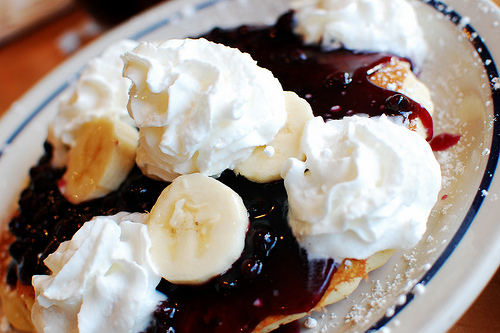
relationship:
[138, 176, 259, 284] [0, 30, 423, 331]
banana on pancake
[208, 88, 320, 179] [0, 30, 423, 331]
banana on pancake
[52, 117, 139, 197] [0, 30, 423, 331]
banana on pancake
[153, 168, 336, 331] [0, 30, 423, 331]
jelly on pancake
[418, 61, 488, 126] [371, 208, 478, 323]
sugar on plate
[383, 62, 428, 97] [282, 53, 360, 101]
pancake with syrup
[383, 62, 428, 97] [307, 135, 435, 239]
pancake with whipped cream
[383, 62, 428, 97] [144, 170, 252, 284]
pancake with banana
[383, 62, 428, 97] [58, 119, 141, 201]
pancake with banana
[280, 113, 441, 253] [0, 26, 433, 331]
cream on pancakes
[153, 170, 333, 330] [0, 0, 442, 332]
blueberry glaze on pancake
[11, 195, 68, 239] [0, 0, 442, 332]
blueberry glaze on pancake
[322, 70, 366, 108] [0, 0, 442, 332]
blueberry glaze on pancake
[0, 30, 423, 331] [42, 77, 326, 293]
pancake are banana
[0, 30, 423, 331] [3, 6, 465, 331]
pancake are blueberry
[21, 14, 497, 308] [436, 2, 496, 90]
plate with rim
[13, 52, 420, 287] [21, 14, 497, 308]
breakfast food on a plate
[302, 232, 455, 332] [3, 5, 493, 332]
sugar on a plate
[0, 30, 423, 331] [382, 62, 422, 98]
pancake has powdered sugar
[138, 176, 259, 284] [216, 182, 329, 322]
banana on blueberry sauce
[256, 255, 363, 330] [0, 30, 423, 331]
side of pancake